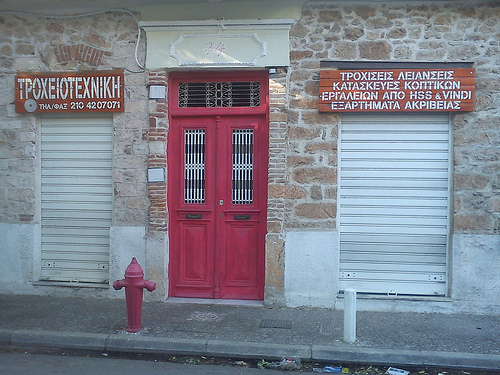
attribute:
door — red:
[163, 65, 273, 311]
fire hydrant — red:
[113, 257, 160, 337]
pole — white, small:
[340, 286, 362, 343]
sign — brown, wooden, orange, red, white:
[317, 69, 481, 117]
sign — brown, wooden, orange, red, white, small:
[16, 68, 126, 116]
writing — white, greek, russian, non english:
[320, 71, 472, 109]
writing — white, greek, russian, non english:
[17, 77, 122, 110]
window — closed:
[332, 110, 460, 304]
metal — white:
[338, 112, 452, 300]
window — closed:
[28, 112, 117, 295]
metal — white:
[40, 115, 108, 287]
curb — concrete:
[6, 323, 499, 374]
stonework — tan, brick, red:
[1, 6, 498, 236]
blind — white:
[226, 127, 254, 205]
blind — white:
[183, 127, 208, 208]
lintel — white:
[138, 14, 298, 75]